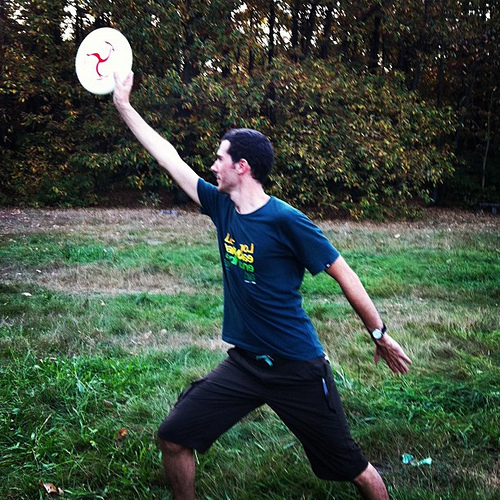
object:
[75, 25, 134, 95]
frisbee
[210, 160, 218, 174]
nose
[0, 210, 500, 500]
untrimmed grass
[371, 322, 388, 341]
wrist watch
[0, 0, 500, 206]
trees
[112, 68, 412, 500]
man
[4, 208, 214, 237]
grass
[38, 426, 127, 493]
leaves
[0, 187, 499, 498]
ground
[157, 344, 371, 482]
black shorts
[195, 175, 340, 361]
shirt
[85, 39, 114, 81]
image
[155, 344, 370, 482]
shorts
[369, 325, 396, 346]
wrist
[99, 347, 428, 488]
grass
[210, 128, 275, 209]
head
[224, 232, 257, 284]
image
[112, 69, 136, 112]
hand